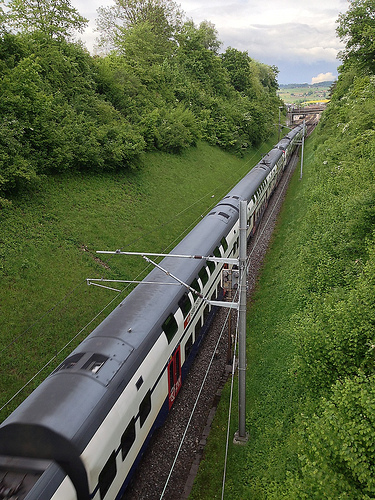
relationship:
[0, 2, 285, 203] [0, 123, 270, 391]
trees on hill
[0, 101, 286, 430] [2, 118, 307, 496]
hill by train